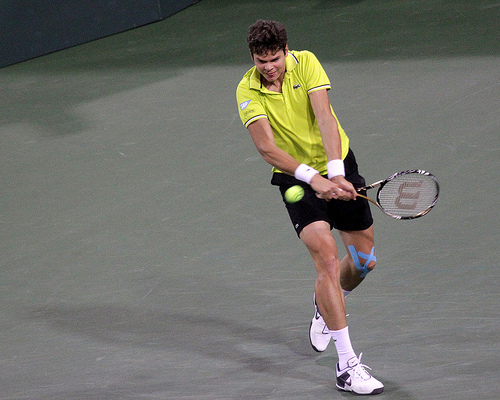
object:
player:
[234, 17, 389, 396]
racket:
[316, 169, 441, 222]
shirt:
[234, 49, 350, 174]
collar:
[249, 66, 294, 96]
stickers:
[347, 244, 377, 277]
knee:
[347, 250, 378, 277]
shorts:
[269, 149, 374, 237]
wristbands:
[293, 159, 345, 184]